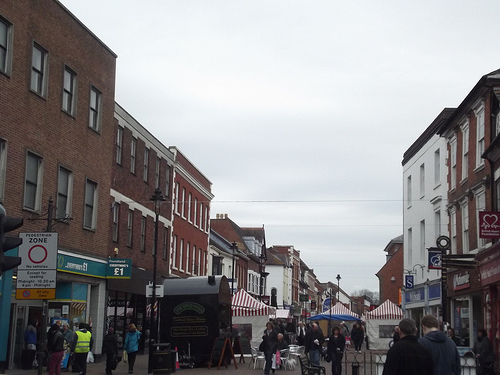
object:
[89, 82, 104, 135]
window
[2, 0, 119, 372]
building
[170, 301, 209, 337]
sign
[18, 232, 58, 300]
sign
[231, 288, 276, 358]
tent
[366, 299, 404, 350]
tent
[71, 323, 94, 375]
man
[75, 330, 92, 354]
vest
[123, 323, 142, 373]
woman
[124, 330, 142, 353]
jacket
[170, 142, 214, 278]
building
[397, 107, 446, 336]
building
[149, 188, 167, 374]
street light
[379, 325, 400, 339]
window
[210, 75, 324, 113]
cloud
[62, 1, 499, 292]
sky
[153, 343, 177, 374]
trash can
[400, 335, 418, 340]
collar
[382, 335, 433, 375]
jacket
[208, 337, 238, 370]
sign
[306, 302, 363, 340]
tent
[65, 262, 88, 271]
business names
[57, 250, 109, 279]
banner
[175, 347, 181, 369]
safety cone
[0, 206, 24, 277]
traffic light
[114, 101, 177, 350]
buildings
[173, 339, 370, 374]
street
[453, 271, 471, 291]
store sign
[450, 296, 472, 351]
entrance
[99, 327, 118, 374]
people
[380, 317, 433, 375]
men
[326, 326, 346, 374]
woman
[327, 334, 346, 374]
suit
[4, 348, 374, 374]
sidewalk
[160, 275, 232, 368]
cabin